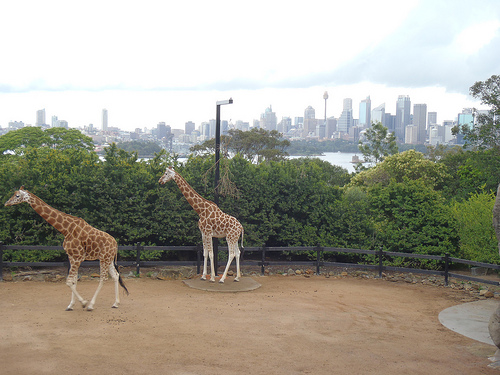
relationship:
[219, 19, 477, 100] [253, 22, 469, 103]
cloud in sky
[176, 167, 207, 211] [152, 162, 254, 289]
neck of giraffe